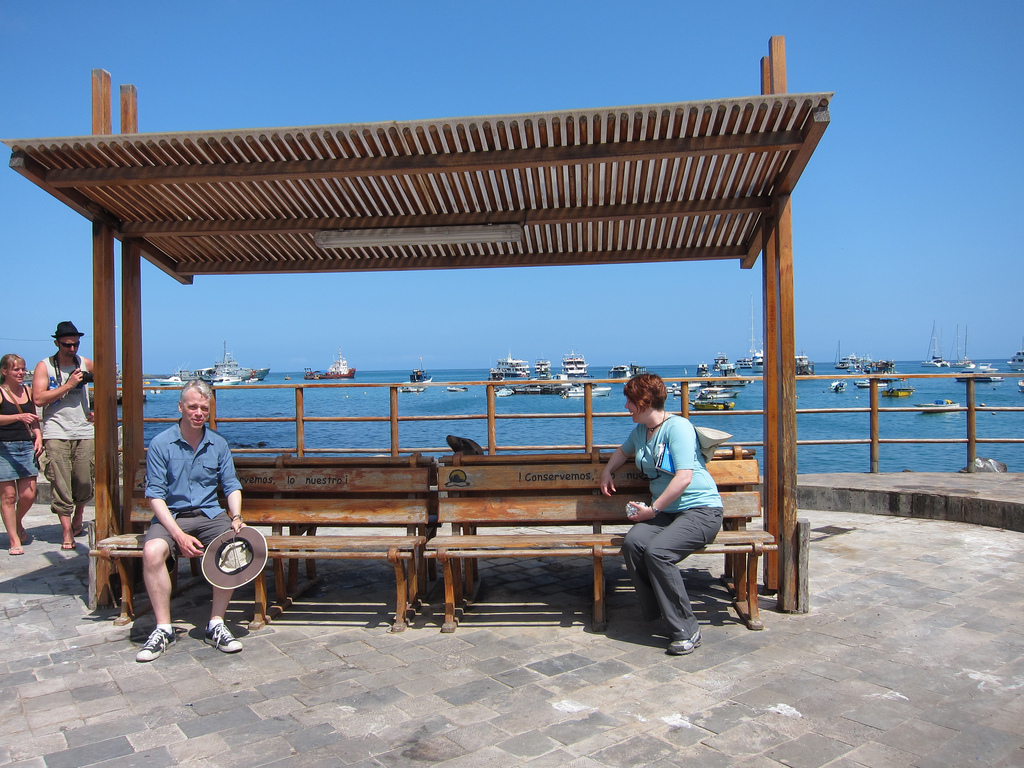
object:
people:
[0, 321, 725, 662]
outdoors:
[0, 0, 1024, 768]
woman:
[600, 372, 724, 656]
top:
[621, 415, 723, 513]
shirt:
[143, 417, 242, 525]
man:
[135, 378, 247, 663]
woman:
[0, 354, 43, 556]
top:
[0, 383, 36, 443]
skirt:
[0, 441, 39, 484]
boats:
[154, 289, 913, 411]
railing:
[142, 375, 764, 486]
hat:
[50, 321, 86, 339]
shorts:
[143, 509, 249, 565]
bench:
[87, 451, 445, 632]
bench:
[424, 445, 778, 633]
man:
[32, 315, 100, 551]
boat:
[17, 301, 1022, 416]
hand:
[176, 521, 248, 559]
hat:
[202, 526, 270, 590]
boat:
[914, 395, 961, 414]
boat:
[854, 359, 915, 397]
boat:
[829, 341, 916, 398]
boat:
[666, 352, 754, 410]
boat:
[665, 292, 816, 411]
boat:
[488, 349, 611, 399]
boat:
[395, 357, 431, 392]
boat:
[304, 346, 356, 380]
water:
[0, 358, 1024, 477]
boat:
[158, 339, 290, 387]